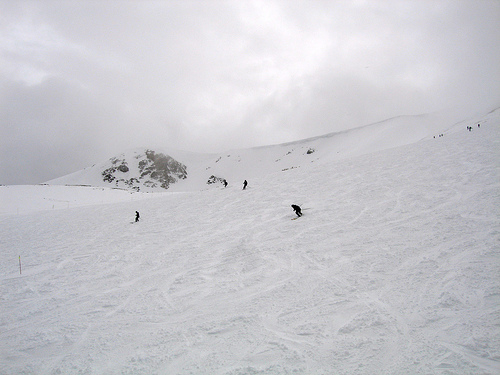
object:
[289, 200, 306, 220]
person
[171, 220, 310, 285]
white snow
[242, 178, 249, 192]
person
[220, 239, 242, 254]
snow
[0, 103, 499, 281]
mountain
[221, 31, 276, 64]
cloud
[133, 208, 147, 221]
black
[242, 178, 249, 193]
black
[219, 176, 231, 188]
skier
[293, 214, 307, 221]
skis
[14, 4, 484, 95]
sky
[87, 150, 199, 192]
outcrop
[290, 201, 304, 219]
black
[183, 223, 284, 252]
field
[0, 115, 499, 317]
hill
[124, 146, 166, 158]
top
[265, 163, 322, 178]
distance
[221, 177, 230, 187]
distance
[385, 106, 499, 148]
mountain top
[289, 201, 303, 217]
outdoors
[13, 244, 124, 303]
paths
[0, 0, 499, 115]
background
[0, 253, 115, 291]
ground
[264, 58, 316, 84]
sunlight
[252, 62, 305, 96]
behind clouds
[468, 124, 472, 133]
skier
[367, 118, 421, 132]
distance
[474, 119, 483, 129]
skier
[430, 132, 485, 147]
distance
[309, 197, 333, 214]
track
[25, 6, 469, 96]
day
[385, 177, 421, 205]
tracks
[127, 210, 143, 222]
people